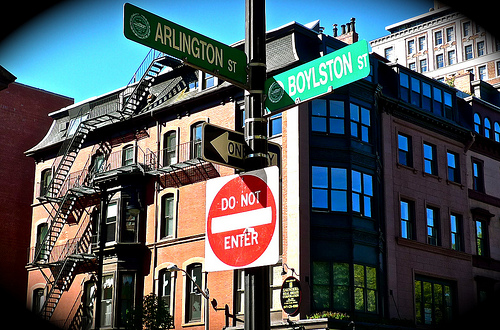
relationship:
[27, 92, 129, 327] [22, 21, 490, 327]
escape on building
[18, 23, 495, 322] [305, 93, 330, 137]
window on building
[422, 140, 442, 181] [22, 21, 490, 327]
window on building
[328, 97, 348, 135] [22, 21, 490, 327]
window on building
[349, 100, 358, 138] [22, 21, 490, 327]
window on building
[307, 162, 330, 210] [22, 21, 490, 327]
window on building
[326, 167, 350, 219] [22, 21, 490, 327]
window on building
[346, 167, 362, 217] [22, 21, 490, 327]
window on building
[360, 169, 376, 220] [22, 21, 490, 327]
window on building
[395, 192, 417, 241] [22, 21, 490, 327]
window on building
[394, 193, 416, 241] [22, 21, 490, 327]
window of building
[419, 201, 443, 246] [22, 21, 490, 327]
window of building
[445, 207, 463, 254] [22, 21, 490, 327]
window of building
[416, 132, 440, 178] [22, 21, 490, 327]
window of building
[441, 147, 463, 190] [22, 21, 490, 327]
window of building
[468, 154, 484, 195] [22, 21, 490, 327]
window of building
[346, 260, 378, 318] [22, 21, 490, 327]
window of building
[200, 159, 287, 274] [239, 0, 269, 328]
sign on pole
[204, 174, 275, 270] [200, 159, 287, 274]
circle on sign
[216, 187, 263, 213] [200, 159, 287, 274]
writing on sign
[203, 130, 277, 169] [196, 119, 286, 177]
arrow on sign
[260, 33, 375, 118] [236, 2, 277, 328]
street sign on pole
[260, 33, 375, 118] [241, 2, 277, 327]
street sign on pole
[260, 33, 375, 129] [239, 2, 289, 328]
street sign on pole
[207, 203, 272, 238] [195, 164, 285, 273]
line on sign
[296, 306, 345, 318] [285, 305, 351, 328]
plants on column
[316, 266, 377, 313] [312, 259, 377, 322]
reflection in windows